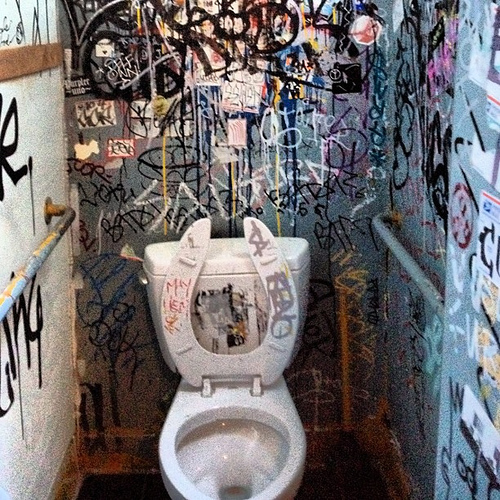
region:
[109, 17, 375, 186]
Grafitti on the wall.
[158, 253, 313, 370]
Grafitti on the toilet set.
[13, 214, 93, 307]
A railing with grafitti on the wall.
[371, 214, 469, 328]
A railing on the right side of wall.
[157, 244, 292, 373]
The toilet seat is up.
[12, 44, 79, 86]
A wood board across the side wall.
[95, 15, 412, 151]
The wall is full of grafitti.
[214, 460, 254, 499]
Water in the toilet.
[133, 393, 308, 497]
The toilet is white.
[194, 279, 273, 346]
Grafitti on the toilet water bowl.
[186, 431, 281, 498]
this is a toilet bowl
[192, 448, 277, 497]
there is not a lot of water in the bowl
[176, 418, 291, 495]
the bowl looks empty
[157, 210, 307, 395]
the seat is lifted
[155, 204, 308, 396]
this is the underside of the toilet seat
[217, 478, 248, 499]
this is the drain hole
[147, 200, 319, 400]
there is graffiti on the seat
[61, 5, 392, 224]
there is graffiti on the wall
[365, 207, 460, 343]
this is a hand rail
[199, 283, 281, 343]
graffiti on the toilet tank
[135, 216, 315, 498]
white toilet with raised seat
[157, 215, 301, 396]
raised toilet seat covered with graffiti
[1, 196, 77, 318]
old, corroded metal rail attached to wall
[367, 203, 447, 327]
bluish-green metal pipe fastened to wall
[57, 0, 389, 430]
back wall covered in graffiti that is mostly text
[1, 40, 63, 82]
wooden board hanging on wall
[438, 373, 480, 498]
drawing that resembles Bart Simpson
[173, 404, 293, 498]
bowl area of white toilet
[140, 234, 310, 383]
white toilet tank with lid and graffiti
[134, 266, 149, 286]
silver toilet flushing handle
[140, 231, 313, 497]
the toilet is against the wall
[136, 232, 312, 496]
the toilet is white in color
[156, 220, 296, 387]
the toilet seat is up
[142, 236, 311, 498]
the toilet is made of ceramic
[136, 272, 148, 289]
the handle is made of metal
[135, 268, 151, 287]
the handle is made of steel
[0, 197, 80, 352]
a handle is on the wall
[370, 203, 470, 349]
a handle is on the wall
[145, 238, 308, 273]
a lid is on the tank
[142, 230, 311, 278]
the lid is made of ceramic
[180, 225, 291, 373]
the lid of a toilet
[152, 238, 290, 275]
the lid of a tank of a toilet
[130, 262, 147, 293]
the flusher of a toilet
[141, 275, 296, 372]
the tank of a toilet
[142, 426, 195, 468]
the rim of a toilet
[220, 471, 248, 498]
the hole of a toilet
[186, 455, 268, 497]
the water of a toilet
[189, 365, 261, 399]
the hinges of a toilet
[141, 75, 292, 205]
a bunch of painted graffiti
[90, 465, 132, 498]
the floor of a toilet